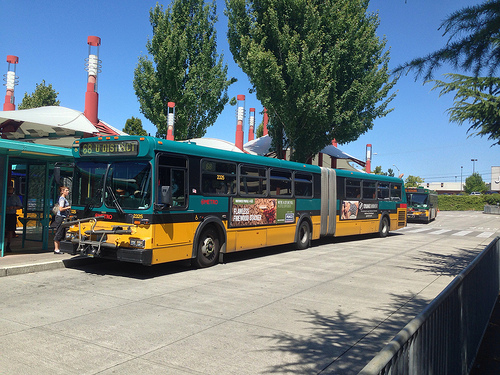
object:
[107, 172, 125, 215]
wiper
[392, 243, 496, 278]
tree shdows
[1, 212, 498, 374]
pavement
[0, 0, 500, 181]
sky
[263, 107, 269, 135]
pole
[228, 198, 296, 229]
advertisement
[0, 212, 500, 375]
ground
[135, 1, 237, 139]
tree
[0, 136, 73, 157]
blue trim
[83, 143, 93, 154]
number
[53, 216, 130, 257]
bike rack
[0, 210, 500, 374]
driveway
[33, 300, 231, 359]
tile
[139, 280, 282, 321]
tile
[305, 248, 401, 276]
tile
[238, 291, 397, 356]
tile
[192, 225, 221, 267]
tire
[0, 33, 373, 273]
bus station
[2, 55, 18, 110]
pole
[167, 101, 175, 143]
pole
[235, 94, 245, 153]
pole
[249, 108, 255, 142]
pole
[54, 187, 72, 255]
woman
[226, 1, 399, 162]
large tree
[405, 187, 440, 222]
bus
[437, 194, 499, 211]
bushes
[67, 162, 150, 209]
windshield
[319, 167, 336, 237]
connector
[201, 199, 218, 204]
lettering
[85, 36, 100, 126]
red poles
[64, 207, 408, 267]
yellow bottom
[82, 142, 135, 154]
sign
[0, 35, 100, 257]
building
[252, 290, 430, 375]
shadow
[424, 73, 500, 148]
tree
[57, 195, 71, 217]
shirt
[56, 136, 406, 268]
bus